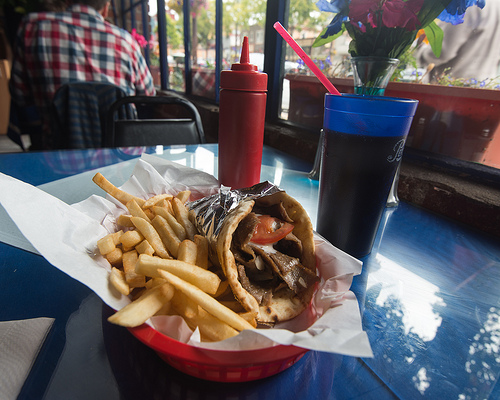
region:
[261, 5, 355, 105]
red straw in cup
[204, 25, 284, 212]
red ketchup bottle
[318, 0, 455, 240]
vase of flowers on table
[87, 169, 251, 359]
fries in red container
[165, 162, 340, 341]
gyro in red container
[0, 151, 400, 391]
white paper under food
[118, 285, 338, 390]
red food container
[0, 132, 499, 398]
blue table top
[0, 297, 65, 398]
white paper napkin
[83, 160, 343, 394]
a plate of food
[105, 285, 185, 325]
this is a piece of fried potato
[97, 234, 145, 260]
this is a piece of fried potato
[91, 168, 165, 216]
this is a piece of fried potato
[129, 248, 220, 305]
this is a piece of fried potato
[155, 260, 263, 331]
this is a piece of fried potato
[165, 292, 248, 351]
this is a piece of fried potato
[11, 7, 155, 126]
back of checkered shirt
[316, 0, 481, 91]
flowers in glass vase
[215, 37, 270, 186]
red plastic ketchup container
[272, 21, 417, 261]
red straw in blue cup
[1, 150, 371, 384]
white paper in red basket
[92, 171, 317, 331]
food in white paper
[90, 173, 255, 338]
pile of french fries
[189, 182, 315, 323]
tortilla wrapped in tin foil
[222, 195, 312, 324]
tomato and meat in flat bread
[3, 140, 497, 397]
light reflection on blue table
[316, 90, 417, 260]
the blue plastic cup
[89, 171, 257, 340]
the pile of fries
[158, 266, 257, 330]
a single piece of french fry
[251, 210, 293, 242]
the piece of sliced tomato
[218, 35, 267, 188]
the red ketchup bottle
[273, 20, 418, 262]
the red straw in the blue cup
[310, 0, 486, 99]
the flowers in the vase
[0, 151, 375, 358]
the thin paper under the food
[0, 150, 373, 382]
the food in a red basket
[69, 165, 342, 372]
this is food in a plate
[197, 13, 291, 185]
this is a bottle of sauce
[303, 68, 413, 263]
this is a glass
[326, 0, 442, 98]
this is a flower vase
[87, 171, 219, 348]
A serving of french fries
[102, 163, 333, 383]
Lunch served in a Red basket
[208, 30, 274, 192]
A plastic ketchup container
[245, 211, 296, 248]
a section of tomato in the lunch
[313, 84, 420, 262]
soda served in a blue cup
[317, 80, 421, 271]
A blue plastic cup on the table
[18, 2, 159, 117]
The back of a man in a checkered shirt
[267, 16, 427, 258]
A blue cup with a straw sticking out of it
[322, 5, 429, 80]
Some flowers in a glass vase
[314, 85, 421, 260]
dark blue plastic cup on blue table top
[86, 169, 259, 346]
fries in red basket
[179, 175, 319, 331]
gyro wrapped in tin foil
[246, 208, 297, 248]
red tomato slice in gyro sandwich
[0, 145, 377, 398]
red basket holding food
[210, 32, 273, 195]
red ketchup bottle on table top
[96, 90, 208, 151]
black chair in front of blue table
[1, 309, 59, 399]
bottom of folded white paper napkin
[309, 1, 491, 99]
clear vase with multi colored flowers on top of table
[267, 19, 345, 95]
red straw in tall blue plastic cup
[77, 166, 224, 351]
fresh french fries on a red basket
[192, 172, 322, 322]
gyro on a red basket